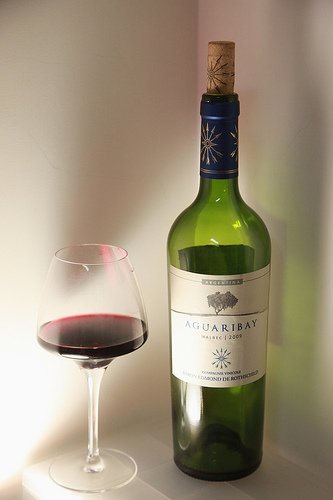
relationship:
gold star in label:
[209, 346, 232, 369] [169, 263, 269, 389]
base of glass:
[50, 448, 138, 492] [37, 238, 151, 493]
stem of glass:
[68, 371, 116, 445] [25, 231, 148, 467]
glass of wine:
[37, 238, 151, 493] [150, 31, 275, 485]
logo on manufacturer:
[204, 288, 238, 315] [182, 313, 262, 332]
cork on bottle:
[205, 40, 235, 94] [156, 88, 290, 498]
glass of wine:
[37, 238, 151, 493] [31, 308, 158, 365]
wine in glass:
[34, 312, 149, 367] [37, 238, 151, 493]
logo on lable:
[206, 291, 238, 315] [166, 261, 270, 385]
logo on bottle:
[206, 291, 238, 315] [165, 39, 272, 483]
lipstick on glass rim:
[100, 245, 114, 271] [52, 235, 134, 270]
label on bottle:
[196, 98, 244, 185] [164, 91, 272, 483]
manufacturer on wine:
[185, 318, 258, 331] [170, 39, 272, 485]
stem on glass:
[83, 370, 104, 462] [19, 224, 198, 498]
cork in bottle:
[205, 40, 235, 94] [167, 96, 271, 483]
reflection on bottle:
[182, 382, 205, 429] [167, 96, 271, 483]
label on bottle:
[169, 263, 269, 389] [161, 36, 274, 366]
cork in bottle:
[205, 38, 234, 95] [155, 92, 272, 483]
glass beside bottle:
[37, 238, 151, 493] [165, 39, 272, 483]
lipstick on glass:
[96, 239, 111, 255] [34, 229, 147, 397]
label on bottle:
[164, 263, 284, 399] [141, 98, 282, 414]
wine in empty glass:
[34, 312, 149, 367] [35, 242, 149, 494]